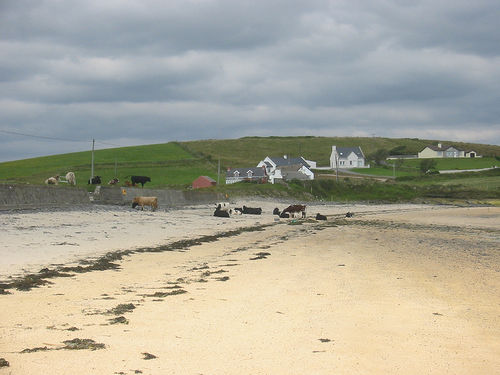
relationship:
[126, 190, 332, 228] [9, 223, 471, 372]
cows on beach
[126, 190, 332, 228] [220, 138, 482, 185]
cows from nearby farm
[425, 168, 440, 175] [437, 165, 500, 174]
car on street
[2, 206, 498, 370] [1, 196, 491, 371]
sand in bunch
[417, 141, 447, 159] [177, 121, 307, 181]
house on hill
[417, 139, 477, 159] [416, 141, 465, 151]
house with roof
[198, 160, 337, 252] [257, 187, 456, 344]
cows are in field